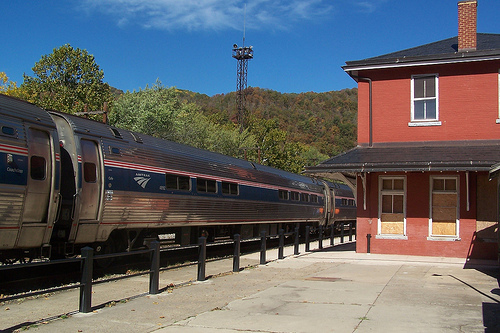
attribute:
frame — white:
[401, 69, 451, 136]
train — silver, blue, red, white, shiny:
[2, 90, 357, 278]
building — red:
[307, 1, 500, 257]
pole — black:
[72, 239, 100, 315]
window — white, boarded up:
[371, 173, 411, 244]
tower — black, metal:
[227, 29, 257, 86]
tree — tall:
[14, 41, 116, 113]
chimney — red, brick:
[454, 0, 482, 55]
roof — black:
[333, 27, 500, 74]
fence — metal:
[22, 218, 354, 290]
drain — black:
[364, 72, 377, 254]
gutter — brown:
[339, 51, 497, 74]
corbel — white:
[336, 171, 372, 212]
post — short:
[144, 234, 164, 298]